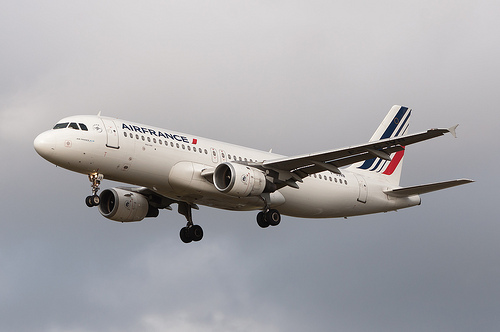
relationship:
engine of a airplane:
[211, 160, 279, 199] [32, 105, 477, 243]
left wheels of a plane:
[175, 221, 205, 242] [27, 96, 470, 232]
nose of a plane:
[21, 136, 84, 159] [28, 128, 73, 165]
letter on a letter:
[120, 120, 132, 132] [131, 121, 143, 133]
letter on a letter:
[120, 120, 132, 132] [139, 124, 148, 134]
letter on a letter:
[120, 120, 132, 132] [159, 127, 178, 140]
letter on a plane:
[120, 120, 132, 132] [27, 96, 470, 232]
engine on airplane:
[212, 162, 266, 198] [26, 97, 480, 247]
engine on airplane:
[89, 182, 159, 230] [20, 64, 477, 273]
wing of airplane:
[202, 124, 458, 194] [32, 105, 477, 243]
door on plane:
[98, 116, 122, 153] [27, 96, 470, 232]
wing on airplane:
[202, 124, 458, 194] [32, 105, 477, 243]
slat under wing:
[309, 157, 346, 176] [33, 100, 475, 245]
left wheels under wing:
[188, 224, 204, 242] [84, 186, 179, 217]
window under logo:
[118, 128, 192, 163] [110, 99, 210, 152]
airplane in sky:
[32, 105, 477, 243] [3, 3, 498, 326]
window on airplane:
[120, 125, 130, 137] [32, 105, 477, 243]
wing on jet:
[256, 121, 461, 188] [27, 67, 483, 268]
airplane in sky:
[32, 105, 477, 243] [135, 19, 377, 137]